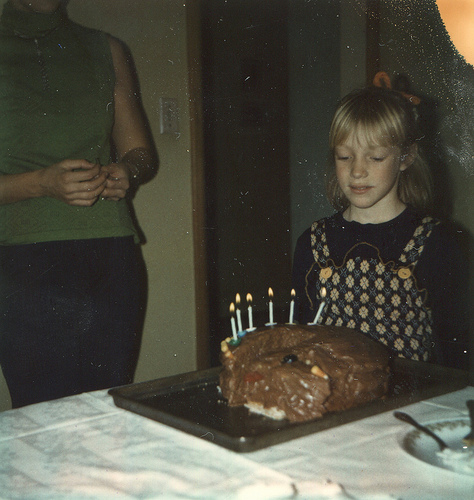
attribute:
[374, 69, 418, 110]
ribbon — orange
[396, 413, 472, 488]
plate — white, round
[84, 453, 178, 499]
tablecloth — white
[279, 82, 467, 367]
girl — celebrating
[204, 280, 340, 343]
candles — six, lit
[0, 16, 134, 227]
shirt — green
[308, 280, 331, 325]
candles — lit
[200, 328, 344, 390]
cake — chocolate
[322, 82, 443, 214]
hair — blond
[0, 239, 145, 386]
pants — black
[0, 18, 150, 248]
shirt — green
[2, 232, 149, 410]
jeans — blue